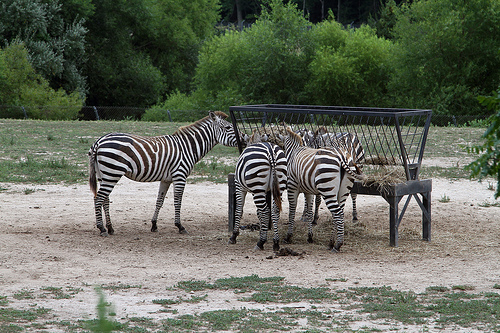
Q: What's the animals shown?
A: Zebra.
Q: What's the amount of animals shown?
A: 4.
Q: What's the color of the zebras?
A: Black and white.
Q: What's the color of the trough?
A: Black.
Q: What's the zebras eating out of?
A: Trough.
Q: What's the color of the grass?
A: Green.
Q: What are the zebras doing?
A: Eating grass.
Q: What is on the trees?
A: Green leaves.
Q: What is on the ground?
A: Dirt.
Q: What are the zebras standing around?
A: A wooden table.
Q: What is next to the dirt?
A: Grass.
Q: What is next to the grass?
A: Trees.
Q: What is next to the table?
A: Zebras.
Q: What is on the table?
A: Grass.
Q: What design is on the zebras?
A: Stripes.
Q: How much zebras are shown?
A: Four.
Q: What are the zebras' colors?
A: Black and white.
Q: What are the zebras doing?
A: Eating.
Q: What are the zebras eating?
A: Hay.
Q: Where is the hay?
A: On the feeding trough.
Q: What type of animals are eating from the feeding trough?
A: Zebras.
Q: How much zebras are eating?
A: Four.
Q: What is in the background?
A: Trees.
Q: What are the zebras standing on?
A: Sand.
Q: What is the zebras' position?
A: Standing up.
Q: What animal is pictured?
A: Zebras.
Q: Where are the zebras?
A: In the field.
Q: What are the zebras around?
A: A feeder.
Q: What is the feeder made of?
A: Metal.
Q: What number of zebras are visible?
A: 4.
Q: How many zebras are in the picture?
A: Four.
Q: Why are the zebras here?
A: They are eating.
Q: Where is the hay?
A: In the feeder.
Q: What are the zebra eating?
A: Hay.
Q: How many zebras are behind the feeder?
A: One.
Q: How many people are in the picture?
A: None.